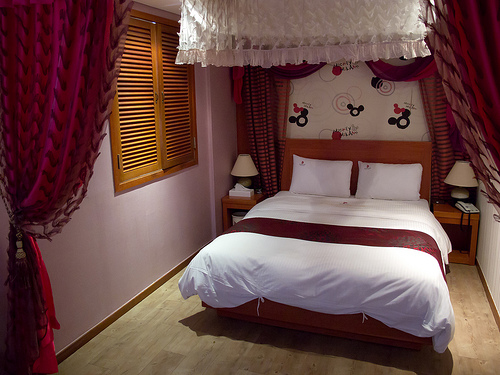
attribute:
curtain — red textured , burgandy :
[4, 0, 136, 372]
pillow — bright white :
[284, 147, 355, 196]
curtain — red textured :
[200, 23, 318, 207]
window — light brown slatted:
[79, 7, 244, 190]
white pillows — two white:
[280, 151, 444, 206]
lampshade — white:
[227, 146, 259, 183]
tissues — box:
[225, 184, 260, 202]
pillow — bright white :
[353, 160, 424, 200]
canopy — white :
[174, 3, 435, 72]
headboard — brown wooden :
[254, 124, 466, 205]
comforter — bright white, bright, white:
[177, 170, 474, 357]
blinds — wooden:
[116, 18, 192, 178]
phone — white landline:
[457, 195, 475, 214]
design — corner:
[294, 91, 426, 145]